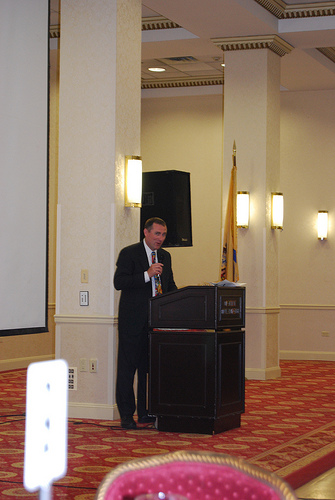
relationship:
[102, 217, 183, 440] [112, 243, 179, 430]
man wearing suit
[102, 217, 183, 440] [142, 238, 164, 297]
man wearing dress shirt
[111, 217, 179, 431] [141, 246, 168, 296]
man wearing tie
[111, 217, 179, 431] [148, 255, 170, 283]
man holding mike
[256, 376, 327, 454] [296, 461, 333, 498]
carpet on ground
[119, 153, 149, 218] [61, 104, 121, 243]
lamp on wall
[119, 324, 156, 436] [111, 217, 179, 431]
pants on man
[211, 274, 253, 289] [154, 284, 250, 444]
paper on podium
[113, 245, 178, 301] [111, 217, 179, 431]
jacket on man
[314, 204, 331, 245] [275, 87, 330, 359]
light mounted to wall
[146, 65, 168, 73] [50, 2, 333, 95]
light mounted into ceiling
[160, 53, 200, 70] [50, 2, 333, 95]
vent in ceiling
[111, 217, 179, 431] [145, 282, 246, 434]
man standing at lectern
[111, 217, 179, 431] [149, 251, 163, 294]
man wearing necktie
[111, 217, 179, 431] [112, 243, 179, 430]
man wearing suit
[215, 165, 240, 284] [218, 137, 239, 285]
flag on flag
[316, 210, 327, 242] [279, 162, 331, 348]
light on wall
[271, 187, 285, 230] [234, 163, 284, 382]
light fixture on pillar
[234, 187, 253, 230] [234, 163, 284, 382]
light fixture on pillar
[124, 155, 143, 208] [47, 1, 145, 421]
lamp on pillar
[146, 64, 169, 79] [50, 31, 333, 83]
light recessed in ceiling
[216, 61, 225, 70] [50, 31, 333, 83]
light recessed in ceiling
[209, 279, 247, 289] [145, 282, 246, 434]
paper on lectern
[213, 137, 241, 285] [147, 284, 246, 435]
flag behind lectern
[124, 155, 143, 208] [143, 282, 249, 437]
lamp above man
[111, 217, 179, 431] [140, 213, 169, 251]
man has head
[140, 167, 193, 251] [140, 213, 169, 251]
object behind head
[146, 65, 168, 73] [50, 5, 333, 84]
light in ceiling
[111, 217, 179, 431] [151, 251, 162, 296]
man has necktie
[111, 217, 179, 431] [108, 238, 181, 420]
man wearing suit